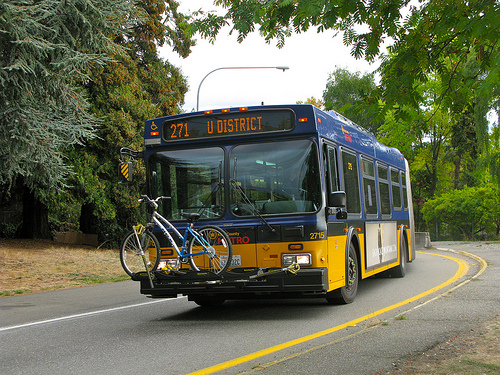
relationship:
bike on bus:
[135, 200, 229, 271] [235, 125, 424, 291]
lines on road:
[244, 344, 285, 359] [68, 337, 146, 360]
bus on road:
[235, 125, 424, 291] [68, 337, 146, 360]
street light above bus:
[196, 55, 285, 103] [235, 125, 424, 291]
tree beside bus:
[67, 209, 95, 237] [235, 125, 424, 291]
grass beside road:
[95, 275, 114, 283] [68, 337, 146, 360]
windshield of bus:
[159, 145, 306, 214] [235, 125, 424, 291]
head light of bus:
[280, 251, 322, 269] [235, 125, 424, 291]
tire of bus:
[330, 233, 369, 305] [235, 125, 424, 291]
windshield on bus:
[159, 145, 306, 214] [235, 125, 424, 291]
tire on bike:
[330, 233, 369, 305] [135, 200, 229, 271]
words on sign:
[225, 120, 267, 134] [194, 120, 286, 133]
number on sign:
[149, 119, 192, 142] [194, 120, 286, 133]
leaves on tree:
[131, 53, 175, 74] [67, 209, 95, 237]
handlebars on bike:
[127, 183, 169, 204] [135, 200, 229, 271]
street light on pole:
[196, 55, 285, 103] [164, 66, 224, 100]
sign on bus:
[194, 120, 286, 133] [235, 125, 424, 291]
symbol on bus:
[303, 235, 328, 248] [235, 125, 424, 291]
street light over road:
[196, 55, 285, 103] [68, 337, 146, 360]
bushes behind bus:
[432, 197, 481, 233] [235, 125, 424, 291]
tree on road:
[67, 209, 95, 237] [68, 337, 146, 360]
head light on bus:
[280, 251, 322, 269] [235, 125, 424, 291]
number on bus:
[149, 119, 192, 142] [235, 125, 424, 291]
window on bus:
[339, 174, 383, 205] [235, 125, 424, 291]